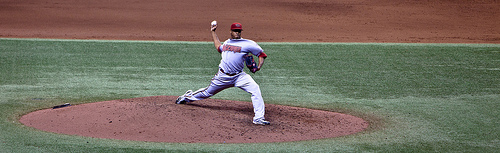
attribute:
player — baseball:
[196, 22, 288, 123]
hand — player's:
[209, 20, 225, 34]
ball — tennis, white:
[209, 19, 222, 28]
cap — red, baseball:
[228, 21, 245, 31]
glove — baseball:
[245, 52, 257, 71]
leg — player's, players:
[184, 73, 221, 104]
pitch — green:
[4, 38, 487, 145]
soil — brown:
[39, 106, 326, 152]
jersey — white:
[218, 36, 248, 88]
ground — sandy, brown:
[27, 92, 353, 152]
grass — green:
[1, 39, 499, 90]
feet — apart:
[178, 90, 280, 127]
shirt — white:
[212, 40, 251, 74]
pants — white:
[191, 67, 268, 120]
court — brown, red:
[6, 2, 489, 57]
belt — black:
[217, 67, 248, 76]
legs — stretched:
[187, 65, 273, 111]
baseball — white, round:
[208, 19, 222, 32]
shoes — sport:
[179, 89, 284, 127]